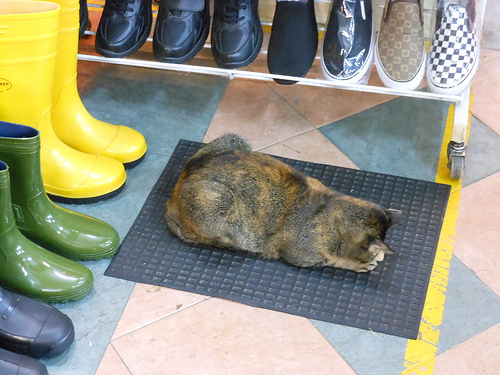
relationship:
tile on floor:
[347, 108, 406, 154] [43, 40, 498, 373]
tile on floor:
[467, 45, 499, 135] [5, 3, 498, 374]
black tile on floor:
[318, 85, 498, 191] [5, 3, 498, 374]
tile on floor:
[123, 284, 214, 325] [38, 1, 478, 372]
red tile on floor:
[453, 184, 498, 276] [103, 310, 444, 372]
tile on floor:
[347, 108, 382, 131] [38, 1, 478, 372]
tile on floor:
[225, 81, 337, 165] [38, 1, 478, 372]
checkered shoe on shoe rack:
[430, 4, 476, 90] [60, 65, 455, 118]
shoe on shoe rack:
[379, 2, 427, 96] [76, 0, 486, 108]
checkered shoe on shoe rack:
[430, 4, 476, 90] [72, 1, 483, 183]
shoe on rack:
[206, 1, 266, 71] [88, 1, 488, 183]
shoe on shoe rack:
[94, 2, 148, 57] [94, 12, 477, 176]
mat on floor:
[384, 207, 466, 333] [146, 290, 271, 365]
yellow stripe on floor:
[395, 87, 477, 367] [217, 72, 497, 372]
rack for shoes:
[61, 0, 483, 188] [222, 32, 477, 99]